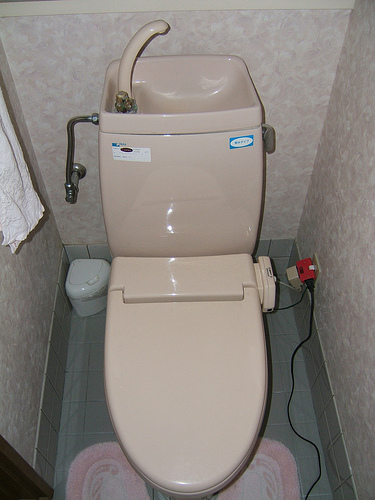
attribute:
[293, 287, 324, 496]
cord — trailing outlet, black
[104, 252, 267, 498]
seat — down, toilet seat, on top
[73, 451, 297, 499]
rug — pink, white, on floor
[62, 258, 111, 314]
bin — in corner, small, plastic, white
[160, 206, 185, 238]
reflection — on toilet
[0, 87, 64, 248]
towel — hanging, white, on top of wall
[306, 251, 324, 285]
outlet — electric, on wall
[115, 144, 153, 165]
sticker — on toilet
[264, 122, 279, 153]
flusher — on toilet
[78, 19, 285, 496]
toilet — in bathroom, white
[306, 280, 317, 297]
plug — in outlet, in box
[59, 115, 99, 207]
plumbing — in wall, for toilet, silver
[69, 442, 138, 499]
carpet — pink, by toilet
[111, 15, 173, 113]
faucet — on tank, behind toilet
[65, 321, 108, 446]
floor — tiled, on the floor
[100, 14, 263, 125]
fountain — on toilet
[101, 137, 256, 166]
stickers — on tank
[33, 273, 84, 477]
tile — on the wall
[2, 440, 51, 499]
door frame — brown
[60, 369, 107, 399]
tile — on top of floor